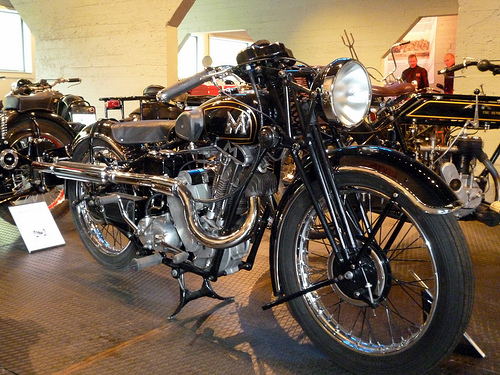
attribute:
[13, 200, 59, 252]
object — white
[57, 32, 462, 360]
bike — black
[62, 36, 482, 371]
motorcycle — black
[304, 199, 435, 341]
spokes — silver, metal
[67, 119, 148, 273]
tire — rear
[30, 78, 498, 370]
motorcycles — display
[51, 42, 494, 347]
bike — chrome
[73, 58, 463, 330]
bike — clean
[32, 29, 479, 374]
motorcycle — black, display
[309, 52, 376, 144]
headlight — large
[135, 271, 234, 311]
kickstand — under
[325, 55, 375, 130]
headlight — large , round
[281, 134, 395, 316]
fender — black, silver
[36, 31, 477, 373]
bike — unused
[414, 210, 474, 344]
tire — black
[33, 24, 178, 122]
wall — white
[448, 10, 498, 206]
wall — white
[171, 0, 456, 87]
wall — white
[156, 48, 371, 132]
handlebars — low slung